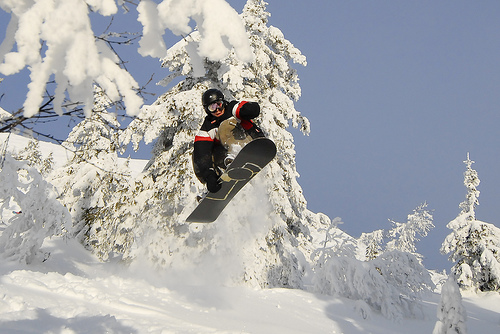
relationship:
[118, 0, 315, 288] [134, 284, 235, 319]
tree covered in snow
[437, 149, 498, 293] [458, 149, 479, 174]
tree with a cross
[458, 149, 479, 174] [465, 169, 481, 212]
cross on top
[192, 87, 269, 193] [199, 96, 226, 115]
man wears goggles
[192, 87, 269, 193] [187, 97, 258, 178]
man wears jacket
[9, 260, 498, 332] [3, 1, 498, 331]
snow on ground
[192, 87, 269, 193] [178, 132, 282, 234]
man on a snowboard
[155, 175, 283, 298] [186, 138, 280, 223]
snow falling falling from board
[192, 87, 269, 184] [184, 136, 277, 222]
man on a snowboard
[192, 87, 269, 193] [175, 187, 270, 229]
man doing tricks on a snowboard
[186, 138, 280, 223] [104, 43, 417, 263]
board in air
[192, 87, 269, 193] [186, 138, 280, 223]
man on a board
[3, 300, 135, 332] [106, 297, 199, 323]
shadow on snow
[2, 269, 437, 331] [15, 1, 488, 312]
snow on trees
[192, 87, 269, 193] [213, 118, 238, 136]
man has knee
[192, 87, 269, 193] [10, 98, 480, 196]
man in mid air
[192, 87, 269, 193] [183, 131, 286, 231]
man on snowboard